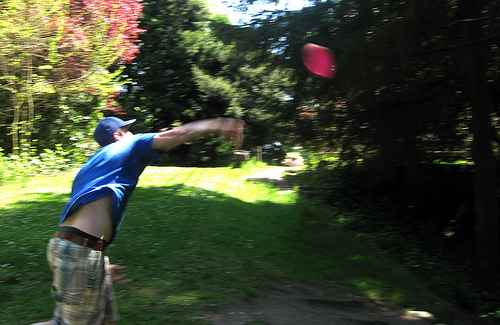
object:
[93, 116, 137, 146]
cap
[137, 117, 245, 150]
arm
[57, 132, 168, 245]
shirt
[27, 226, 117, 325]
shorts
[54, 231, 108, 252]
belt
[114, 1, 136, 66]
leaves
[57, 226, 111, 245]
underwear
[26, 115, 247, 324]
man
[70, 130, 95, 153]
flowers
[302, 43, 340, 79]
football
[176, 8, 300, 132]
trees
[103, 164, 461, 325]
field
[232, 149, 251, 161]
postal box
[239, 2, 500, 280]
forest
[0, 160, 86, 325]
grass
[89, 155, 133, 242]
side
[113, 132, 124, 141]
ear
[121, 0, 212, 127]
tree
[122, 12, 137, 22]
flower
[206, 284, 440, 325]
dirt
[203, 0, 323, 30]
sky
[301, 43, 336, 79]
motion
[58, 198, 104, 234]
back